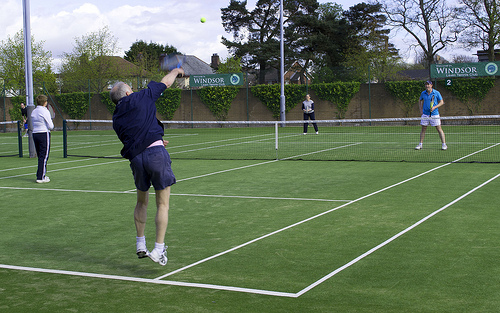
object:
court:
[0, 126, 499, 310]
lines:
[296, 253, 370, 298]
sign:
[189, 73, 244, 87]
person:
[29, 95, 54, 183]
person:
[301, 94, 319, 135]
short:
[130, 145, 176, 191]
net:
[62, 115, 500, 165]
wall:
[0, 75, 500, 131]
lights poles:
[279, 0, 287, 127]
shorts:
[420, 114, 441, 126]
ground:
[323, 171, 366, 210]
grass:
[435, 75, 497, 104]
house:
[159, 55, 216, 89]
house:
[74, 56, 154, 92]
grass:
[57, 92, 93, 120]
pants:
[31, 130, 51, 181]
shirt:
[420, 89, 442, 115]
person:
[20, 102, 32, 137]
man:
[416, 82, 447, 151]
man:
[110, 67, 186, 266]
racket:
[429, 95, 435, 117]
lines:
[157, 251, 235, 280]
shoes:
[147, 246, 168, 266]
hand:
[177, 67, 184, 77]